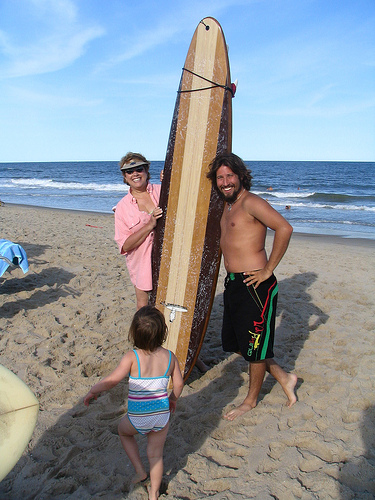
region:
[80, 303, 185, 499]
Child walking on the sand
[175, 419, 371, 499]
Foot prints on the sand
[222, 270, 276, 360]
Black shorts worn by the man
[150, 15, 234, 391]
Brown surf held by two person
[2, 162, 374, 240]
Sea water on the beach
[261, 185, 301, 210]
People swimming on the beach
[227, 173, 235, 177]
Left eye of the man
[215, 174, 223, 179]
Right eye of the man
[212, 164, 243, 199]
Man's face smiling at the camera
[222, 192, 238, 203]
Brown beard of the man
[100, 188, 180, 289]
the shirt is peach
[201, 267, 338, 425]
shadow on the ground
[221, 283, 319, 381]
shadow on the ground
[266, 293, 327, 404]
shadow on the ground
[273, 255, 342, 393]
shadow on the ground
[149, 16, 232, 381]
brown and tan surfboard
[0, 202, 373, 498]
sand with footprints all over it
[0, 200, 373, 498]
sand on the beach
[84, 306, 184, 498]
child in swimsuit walking on the beach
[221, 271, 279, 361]
black green red and yellow swimsuit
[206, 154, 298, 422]
man in a swimsuit with a surfboard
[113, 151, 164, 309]
woman in pink standing by surfboard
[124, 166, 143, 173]
black sungasses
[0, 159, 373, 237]
blue ocean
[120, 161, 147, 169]
visor style hat on woman's head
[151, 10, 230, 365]
the surfboard is brown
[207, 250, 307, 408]
the shorts are black